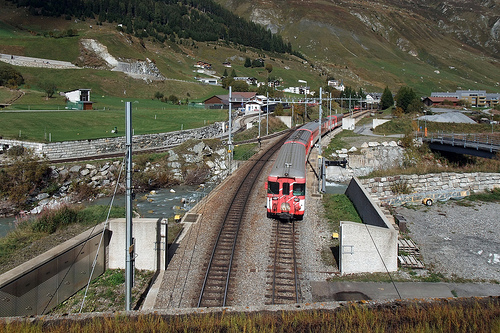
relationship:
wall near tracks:
[359, 171, 500, 207] [199, 134, 304, 305]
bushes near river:
[3, 151, 55, 215] [82, 178, 214, 213]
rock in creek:
[161, 178, 181, 196] [0, 183, 193, 238]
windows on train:
[267, 177, 306, 199] [256, 118, 336, 224]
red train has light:
[266, 114, 345, 220] [272, 197, 302, 213]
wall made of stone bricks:
[374, 169, 480, 205] [446, 177, 473, 190]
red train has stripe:
[266, 114, 345, 220] [296, 197, 304, 215]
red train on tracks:
[266, 114, 345, 220] [263, 219, 313, 310]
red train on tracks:
[266, 114, 345, 220] [193, 139, 275, 304]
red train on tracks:
[266, 114, 345, 220] [265, 235, 305, 286]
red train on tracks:
[266, 114, 345, 220] [259, 217, 311, 305]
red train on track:
[266, 114, 345, 220] [260, 218, 310, 309]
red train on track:
[266, 114, 345, 220] [188, 122, 309, 304]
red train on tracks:
[266, 114, 345, 220] [195, 107, 368, 307]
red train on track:
[266, 114, 345, 220] [238, 100, 324, 300]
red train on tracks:
[266, 114, 345, 220] [197, 111, 339, 303]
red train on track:
[266, 114, 345, 220] [260, 107, 375, 305]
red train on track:
[266, 114, 345, 220] [186, 125, 297, 310]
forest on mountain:
[0, 0, 303, 55] [0, 0, 492, 105]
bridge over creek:
[397, 130, 497, 162] [447, 170, 497, 195]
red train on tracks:
[266, 114, 345, 220] [267, 220, 302, 302]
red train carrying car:
[266, 114, 345, 220] [274, 140, 312, 168]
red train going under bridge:
[266, 114, 345, 220] [6, 290, 498, 330]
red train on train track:
[260, 106, 362, 226] [261, 101, 374, 305]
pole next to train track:
[123, 99, 133, 309] [191, 131, 304, 306]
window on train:
[289, 179, 305, 200] [262, 124, 308, 224]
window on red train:
[267, 181, 280, 194] [266, 114, 345, 220]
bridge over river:
[426, 132, 498, 164] [93, 190, 183, 211]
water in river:
[155, 193, 165, 201] [5, 181, 212, 252]